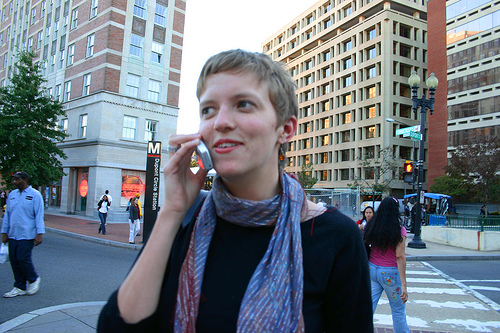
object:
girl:
[98, 48, 378, 332]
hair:
[195, 48, 299, 131]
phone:
[198, 139, 214, 170]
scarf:
[178, 174, 306, 331]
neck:
[217, 155, 281, 199]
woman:
[363, 198, 409, 330]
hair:
[364, 196, 401, 254]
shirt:
[367, 226, 408, 266]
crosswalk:
[372, 260, 499, 331]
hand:
[164, 134, 208, 216]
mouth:
[211, 139, 244, 153]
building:
[2, 1, 186, 225]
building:
[262, 1, 446, 201]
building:
[445, 0, 499, 183]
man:
[2, 171, 46, 299]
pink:
[369, 224, 406, 268]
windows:
[132, 0, 150, 21]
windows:
[127, 34, 150, 62]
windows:
[122, 72, 142, 103]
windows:
[120, 114, 142, 141]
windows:
[314, 58, 334, 81]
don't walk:
[406, 160, 415, 174]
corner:
[44, 212, 143, 251]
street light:
[408, 68, 439, 250]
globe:
[407, 69, 420, 89]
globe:
[426, 72, 440, 92]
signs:
[394, 125, 424, 143]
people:
[98, 188, 115, 236]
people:
[352, 196, 412, 330]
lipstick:
[210, 137, 243, 154]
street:
[365, 258, 497, 331]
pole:
[144, 140, 161, 241]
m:
[148, 141, 161, 153]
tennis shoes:
[2, 284, 27, 298]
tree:
[2, 47, 66, 188]